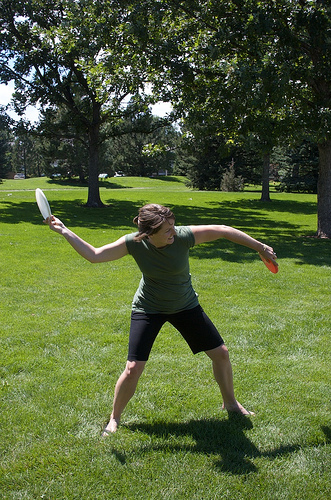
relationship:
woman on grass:
[48, 204, 279, 434] [6, 259, 78, 483]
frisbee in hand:
[26, 191, 55, 215] [41, 217, 65, 231]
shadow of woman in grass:
[142, 422, 247, 472] [6, 259, 78, 483]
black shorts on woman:
[132, 327, 148, 343] [48, 204, 279, 434]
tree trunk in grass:
[64, 73, 116, 216] [6, 259, 78, 483]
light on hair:
[149, 203, 159, 216] [137, 216, 149, 227]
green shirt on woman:
[159, 294, 187, 302] [48, 204, 279, 434]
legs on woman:
[115, 359, 233, 425] [48, 204, 279, 434]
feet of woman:
[107, 411, 253, 438] [48, 204, 279, 434]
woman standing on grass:
[48, 204, 279, 434] [6, 259, 78, 483]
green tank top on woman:
[159, 294, 187, 302] [48, 204, 279, 434]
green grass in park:
[159, 294, 187, 302] [4, 273, 91, 365]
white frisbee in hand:
[38, 198, 49, 206] [41, 217, 65, 231]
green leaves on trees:
[91, 64, 107, 80] [112, 10, 297, 186]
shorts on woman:
[127, 313, 223, 356] [48, 204, 279, 434]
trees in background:
[112, 10, 297, 186] [3, 5, 329, 177]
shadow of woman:
[142, 422, 247, 472] [48, 204, 279, 434]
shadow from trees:
[142, 422, 247, 472] [112, 10, 297, 186]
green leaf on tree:
[159, 294, 187, 302] [64, 73, 116, 216]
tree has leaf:
[64, 73, 116, 216] [16, 110, 26, 115]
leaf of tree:
[16, 110, 26, 115] [64, 73, 116, 216]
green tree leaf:
[159, 294, 187, 302] [16, 110, 26, 115]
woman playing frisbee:
[48, 204, 279, 434] [26, 191, 55, 215]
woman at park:
[48, 204, 279, 434] [4, 273, 91, 365]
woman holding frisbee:
[48, 204, 279, 434] [26, 191, 55, 215]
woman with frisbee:
[48, 204, 279, 434] [26, 191, 55, 215]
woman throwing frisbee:
[48, 204, 279, 434] [26, 191, 55, 215]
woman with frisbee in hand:
[48, 204, 279, 434] [41, 217, 65, 231]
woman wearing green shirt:
[48, 204, 279, 434] [131, 241, 195, 312]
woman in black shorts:
[48, 204, 279, 434] [127, 313, 223, 356]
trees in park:
[112, 10, 297, 186] [4, 273, 91, 365]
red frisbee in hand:
[259, 257, 277, 273] [41, 217, 65, 231]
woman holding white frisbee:
[48, 204, 279, 434] [26, 191, 55, 215]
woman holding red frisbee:
[48, 204, 279, 434] [26, 191, 55, 215]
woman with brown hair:
[48, 204, 279, 434] [137, 216, 149, 227]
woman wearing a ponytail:
[48, 204, 279, 434] [135, 217, 141, 232]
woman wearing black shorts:
[48, 204, 279, 434] [127, 313, 223, 356]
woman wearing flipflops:
[48, 204, 279, 434] [107, 411, 253, 438]